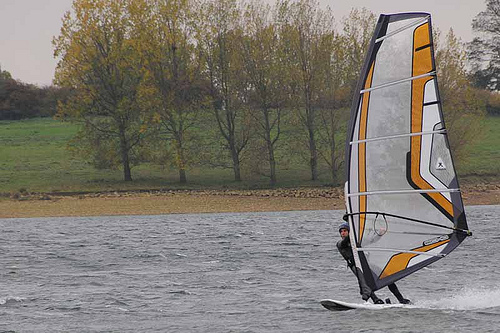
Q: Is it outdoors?
A: Yes, it is outdoors.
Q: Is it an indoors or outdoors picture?
A: It is outdoors.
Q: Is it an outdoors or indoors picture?
A: It is outdoors.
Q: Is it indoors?
A: No, it is outdoors.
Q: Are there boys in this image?
A: No, there are no boys.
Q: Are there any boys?
A: No, there are no boys.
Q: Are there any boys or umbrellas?
A: No, there are no boys or umbrellas.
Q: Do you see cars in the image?
A: No, there are no cars.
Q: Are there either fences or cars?
A: No, there are no cars or fences.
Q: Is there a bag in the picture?
A: No, there are no bags.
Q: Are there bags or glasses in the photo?
A: No, there are no bags or glasses.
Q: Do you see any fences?
A: No, there are no fences.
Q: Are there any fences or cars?
A: No, there are no fences or cars.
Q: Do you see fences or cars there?
A: No, there are no fences or cars.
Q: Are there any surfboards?
A: Yes, there is a surfboard.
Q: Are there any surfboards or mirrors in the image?
A: Yes, there is a surfboard.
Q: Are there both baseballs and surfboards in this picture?
A: No, there is a surfboard but no baseballs.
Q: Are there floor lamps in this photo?
A: No, there are no floor lamps.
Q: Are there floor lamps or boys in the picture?
A: No, there are no floor lamps or boys.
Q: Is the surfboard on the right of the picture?
A: Yes, the surfboard is on the right of the image.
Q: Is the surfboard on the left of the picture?
A: No, the surfboard is on the right of the image.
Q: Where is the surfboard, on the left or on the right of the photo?
A: The surfboard is on the right of the image.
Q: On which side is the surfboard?
A: The surfboard is on the right of the image.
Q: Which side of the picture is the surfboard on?
A: The surfboard is on the right of the image.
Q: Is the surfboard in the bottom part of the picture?
A: Yes, the surfboard is in the bottom of the image.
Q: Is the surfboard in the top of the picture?
A: No, the surfboard is in the bottom of the image.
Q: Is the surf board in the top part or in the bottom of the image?
A: The surf board is in the bottom of the image.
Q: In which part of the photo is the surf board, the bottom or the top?
A: The surf board is in the bottom of the image.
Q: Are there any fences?
A: No, there are no fences.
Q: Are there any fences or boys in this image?
A: No, there are no fences or boys.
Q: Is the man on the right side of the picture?
A: Yes, the man is on the right of the image.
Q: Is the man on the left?
A: No, the man is on the right of the image.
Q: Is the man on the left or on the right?
A: The man is on the right of the image.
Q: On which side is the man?
A: The man is on the right of the image.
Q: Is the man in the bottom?
A: Yes, the man is in the bottom of the image.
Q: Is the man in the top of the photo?
A: No, the man is in the bottom of the image.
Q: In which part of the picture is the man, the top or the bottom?
A: The man is in the bottom of the image.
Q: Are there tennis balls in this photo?
A: No, there are no tennis balls.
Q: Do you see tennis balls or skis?
A: No, there are no tennis balls or skis.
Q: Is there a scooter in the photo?
A: No, there are no scooters.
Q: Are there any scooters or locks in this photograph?
A: No, there are no scooters or locks.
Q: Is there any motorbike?
A: No, there are no motorcycles.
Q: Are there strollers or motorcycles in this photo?
A: No, there are no motorcycles or strollers.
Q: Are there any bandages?
A: No, there are no bandages.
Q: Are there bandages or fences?
A: No, there are no bandages or fences.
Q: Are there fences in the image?
A: No, there are no fences.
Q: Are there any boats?
A: No, there are no boats.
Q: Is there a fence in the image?
A: No, there are no fences.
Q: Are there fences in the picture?
A: No, there are no fences.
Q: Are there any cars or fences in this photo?
A: No, there are no fences or cars.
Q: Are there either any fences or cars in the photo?
A: No, there are no fences or cars.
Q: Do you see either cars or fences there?
A: No, there are no fences or cars.